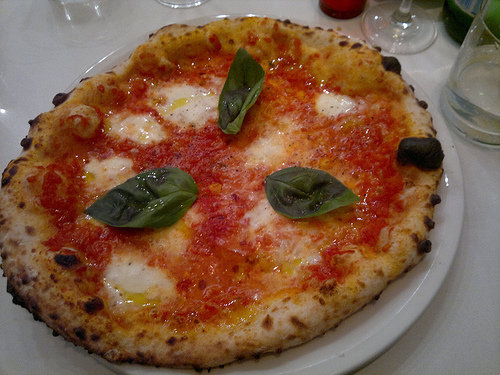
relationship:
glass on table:
[440, 1, 497, 147] [1, 0, 499, 375]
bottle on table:
[441, 1, 500, 48] [1, 0, 499, 375]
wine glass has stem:
[360, 0, 436, 57] [390, 1, 413, 25]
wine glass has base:
[360, 0, 436, 57] [362, 4, 437, 54]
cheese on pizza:
[0, 16, 448, 317] [2, 16, 444, 371]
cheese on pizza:
[103, 108, 169, 148] [2, 16, 444, 371]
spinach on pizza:
[84, 168, 200, 227] [2, 16, 444, 371]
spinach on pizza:
[217, 44, 264, 135] [2, 16, 444, 371]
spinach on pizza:
[263, 167, 360, 219] [2, 16, 444, 371]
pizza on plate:
[2, 16, 444, 371] [63, 11, 464, 373]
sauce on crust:
[41, 35, 403, 321] [0, 14, 446, 371]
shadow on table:
[349, 201, 467, 375] [1, 0, 499, 375]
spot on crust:
[395, 135, 445, 172] [0, 14, 446, 371]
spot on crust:
[428, 191, 442, 204] [0, 14, 446, 371]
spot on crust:
[423, 213, 435, 230] [0, 14, 446, 371]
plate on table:
[63, 11, 464, 373] [1, 0, 499, 375]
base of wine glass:
[362, 4, 437, 54] [360, 0, 436, 57]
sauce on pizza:
[41, 35, 403, 321] [2, 16, 444, 371]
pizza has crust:
[2, 16, 444, 371] [0, 14, 446, 371]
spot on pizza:
[395, 135, 445, 172] [2, 16, 444, 371]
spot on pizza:
[428, 191, 442, 204] [2, 16, 444, 371]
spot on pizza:
[423, 213, 435, 230] [2, 16, 444, 371]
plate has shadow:
[63, 11, 464, 373] [349, 201, 467, 375]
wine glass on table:
[360, 0, 436, 57] [1, 0, 499, 375]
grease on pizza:
[115, 284, 157, 309] [2, 16, 444, 371]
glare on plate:
[84, 45, 121, 73] [63, 11, 464, 373]